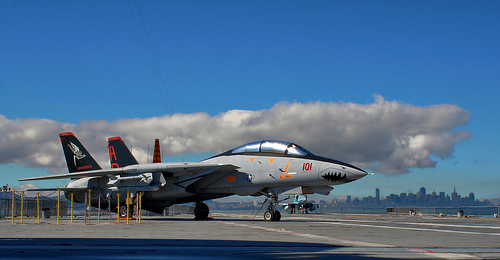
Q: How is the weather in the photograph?
A: It is cloudy.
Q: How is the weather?
A: It is cloudy.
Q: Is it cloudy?
A: Yes, it is cloudy.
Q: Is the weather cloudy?
A: Yes, it is cloudy.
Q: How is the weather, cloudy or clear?
A: It is cloudy.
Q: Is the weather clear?
A: No, it is cloudy.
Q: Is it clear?
A: No, it is cloudy.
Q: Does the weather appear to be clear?
A: No, it is cloudy.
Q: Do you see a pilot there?
A: No, there are no pilots.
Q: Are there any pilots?
A: No, there are no pilots.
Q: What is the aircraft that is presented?
A: The aircraft is a jet.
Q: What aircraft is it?
A: The aircraft is a jet.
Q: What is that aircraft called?
A: This is a jet.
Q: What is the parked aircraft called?
A: The aircraft is a jet.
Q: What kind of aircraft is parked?
A: The aircraft is a jet.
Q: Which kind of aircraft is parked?
A: The aircraft is a jet.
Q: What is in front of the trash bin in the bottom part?
A: The jet is in front of the trash bin.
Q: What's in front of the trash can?
A: The jet is in front of the trash bin.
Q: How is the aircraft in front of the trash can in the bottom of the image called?
A: The aircraft is a jet.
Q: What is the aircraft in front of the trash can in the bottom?
A: The aircraft is a jet.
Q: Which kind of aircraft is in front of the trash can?
A: The aircraft is a jet.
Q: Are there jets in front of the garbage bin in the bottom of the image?
A: Yes, there is a jet in front of the garbage bin.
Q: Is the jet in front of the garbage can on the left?
A: Yes, the jet is in front of the garbage bin.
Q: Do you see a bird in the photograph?
A: No, there are no birds.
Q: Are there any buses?
A: No, there are no buses.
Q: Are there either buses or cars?
A: No, there are no buses or cars.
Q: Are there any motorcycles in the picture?
A: No, there are no motorcycles.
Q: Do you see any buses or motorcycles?
A: No, there are no motorcycles or buses.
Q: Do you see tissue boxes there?
A: No, there are no tissue boxes.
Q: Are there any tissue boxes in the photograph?
A: No, there are no tissue boxes.